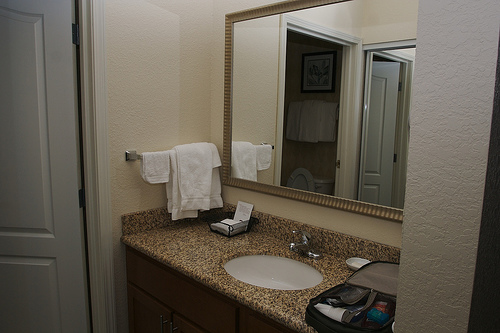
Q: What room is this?
A: It is a bathroom.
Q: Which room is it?
A: It is a bathroom.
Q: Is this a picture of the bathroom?
A: Yes, it is showing the bathroom.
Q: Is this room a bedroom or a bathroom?
A: It is a bathroom.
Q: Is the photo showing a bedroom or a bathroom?
A: It is showing a bathroom.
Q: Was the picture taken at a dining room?
A: No, the picture was taken in a bathroom.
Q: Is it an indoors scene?
A: Yes, it is indoors.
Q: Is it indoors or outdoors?
A: It is indoors.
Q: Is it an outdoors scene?
A: No, it is indoors.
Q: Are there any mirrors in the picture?
A: Yes, there is a mirror.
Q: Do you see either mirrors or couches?
A: Yes, there is a mirror.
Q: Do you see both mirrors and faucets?
A: Yes, there are both a mirror and a faucet.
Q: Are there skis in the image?
A: No, there are no skis.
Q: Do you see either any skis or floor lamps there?
A: No, there are no skis or floor lamps.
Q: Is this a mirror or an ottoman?
A: This is a mirror.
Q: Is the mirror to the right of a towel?
A: Yes, the mirror is to the right of a towel.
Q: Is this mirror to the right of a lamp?
A: No, the mirror is to the right of a towel.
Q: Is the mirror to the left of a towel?
A: No, the mirror is to the right of a towel.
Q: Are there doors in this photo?
A: Yes, there is a door.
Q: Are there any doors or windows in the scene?
A: Yes, there is a door.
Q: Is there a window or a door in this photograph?
A: Yes, there is a door.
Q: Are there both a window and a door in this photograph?
A: No, there is a door but no windows.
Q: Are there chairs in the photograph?
A: No, there are no chairs.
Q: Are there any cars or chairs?
A: No, there are no chairs or cars.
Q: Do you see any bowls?
A: No, there are no bowls.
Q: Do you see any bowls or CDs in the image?
A: No, there are no bowls or cds.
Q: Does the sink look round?
A: Yes, the sink is round.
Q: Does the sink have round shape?
A: Yes, the sink is round.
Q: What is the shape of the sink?
A: The sink is round.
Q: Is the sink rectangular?
A: No, the sink is round.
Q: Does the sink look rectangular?
A: No, the sink is round.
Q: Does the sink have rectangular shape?
A: No, the sink is round.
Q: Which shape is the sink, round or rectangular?
A: The sink is round.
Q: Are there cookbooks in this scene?
A: No, there are no cookbooks.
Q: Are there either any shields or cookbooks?
A: No, there are no cookbooks or shields.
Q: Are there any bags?
A: Yes, there is a bag.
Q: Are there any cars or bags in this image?
A: Yes, there is a bag.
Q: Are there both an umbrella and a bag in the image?
A: No, there is a bag but no umbrellas.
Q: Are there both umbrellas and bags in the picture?
A: No, there is a bag but no umbrellas.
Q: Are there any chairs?
A: No, there are no chairs.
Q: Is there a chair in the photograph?
A: No, there are no chairs.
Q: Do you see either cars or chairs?
A: No, there are no chairs or cars.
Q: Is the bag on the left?
A: No, the bag is on the right of the image.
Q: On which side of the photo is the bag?
A: The bag is on the right of the image.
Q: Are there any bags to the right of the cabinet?
A: Yes, there is a bag to the right of the cabinet.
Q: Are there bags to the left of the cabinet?
A: No, the bag is to the right of the cabinet.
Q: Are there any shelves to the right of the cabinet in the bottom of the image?
A: No, there is a bag to the right of the cabinet.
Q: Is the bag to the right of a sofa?
A: No, the bag is to the right of the cabinet.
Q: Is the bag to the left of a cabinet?
A: No, the bag is to the right of a cabinet.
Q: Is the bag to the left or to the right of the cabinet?
A: The bag is to the right of the cabinet.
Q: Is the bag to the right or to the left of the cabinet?
A: The bag is to the right of the cabinet.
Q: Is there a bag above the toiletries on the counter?
A: Yes, there is a bag above the toiletries.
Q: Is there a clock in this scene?
A: No, there are no clocks.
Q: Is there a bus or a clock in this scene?
A: No, there are no clocks or buses.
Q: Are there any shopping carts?
A: No, there are no shopping carts.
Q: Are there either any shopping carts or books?
A: No, there are no shopping carts or books.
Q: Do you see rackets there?
A: No, there are no rackets.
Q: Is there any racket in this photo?
A: No, there are no rackets.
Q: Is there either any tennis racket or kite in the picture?
A: No, there are no rackets or kites.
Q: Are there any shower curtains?
A: No, there are no shower curtains.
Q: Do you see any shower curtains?
A: No, there are no shower curtains.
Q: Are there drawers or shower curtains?
A: No, there are no shower curtains or drawers.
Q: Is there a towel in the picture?
A: Yes, there is a towel.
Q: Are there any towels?
A: Yes, there is a towel.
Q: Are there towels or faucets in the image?
A: Yes, there is a towel.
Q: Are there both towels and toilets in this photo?
A: Yes, there are both a towel and a toilet.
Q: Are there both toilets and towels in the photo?
A: Yes, there are both a towel and a toilet.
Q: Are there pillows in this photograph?
A: No, there are no pillows.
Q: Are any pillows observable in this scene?
A: No, there are no pillows.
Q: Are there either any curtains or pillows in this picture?
A: No, there are no pillows or curtains.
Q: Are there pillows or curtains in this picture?
A: No, there are no pillows or curtains.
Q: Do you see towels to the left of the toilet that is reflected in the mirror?
A: Yes, there is a towel to the left of the toilet.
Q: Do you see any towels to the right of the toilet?
A: No, the towel is to the left of the toilet.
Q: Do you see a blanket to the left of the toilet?
A: No, there is a towel to the left of the toilet.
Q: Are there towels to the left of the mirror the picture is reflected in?
A: Yes, there is a towel to the left of the mirror.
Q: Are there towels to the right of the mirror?
A: No, the towel is to the left of the mirror.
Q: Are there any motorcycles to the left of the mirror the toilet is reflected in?
A: No, there is a towel to the left of the mirror.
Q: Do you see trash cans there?
A: No, there are no trash cans.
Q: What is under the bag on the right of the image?
A: The toiletries are under the bag.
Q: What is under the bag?
A: The toiletries are under the bag.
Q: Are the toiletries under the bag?
A: Yes, the toiletries are under the bag.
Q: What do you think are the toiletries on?
A: The toiletries are on the counter.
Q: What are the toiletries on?
A: The toiletries are on the counter.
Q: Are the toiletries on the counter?
A: Yes, the toiletries are on the counter.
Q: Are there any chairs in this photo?
A: No, there are no chairs.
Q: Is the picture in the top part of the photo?
A: Yes, the picture is in the top of the image.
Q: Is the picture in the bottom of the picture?
A: No, the picture is in the top of the image.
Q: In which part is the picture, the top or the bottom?
A: The picture is in the top of the image.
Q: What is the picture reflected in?
A: The picture is reflected in the mirror.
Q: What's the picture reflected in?
A: The picture is reflected in the mirror.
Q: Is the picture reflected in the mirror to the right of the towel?
A: Yes, the picture is reflected in the mirror.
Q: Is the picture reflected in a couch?
A: No, the picture is reflected in the mirror.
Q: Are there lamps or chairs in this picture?
A: No, there are no chairs or lamps.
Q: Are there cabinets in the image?
A: Yes, there is a cabinet.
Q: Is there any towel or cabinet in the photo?
A: Yes, there is a cabinet.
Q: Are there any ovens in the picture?
A: No, there are no ovens.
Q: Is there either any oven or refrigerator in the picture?
A: No, there are no ovens or refrigerators.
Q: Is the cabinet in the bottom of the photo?
A: Yes, the cabinet is in the bottom of the image.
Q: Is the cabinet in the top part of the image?
A: No, the cabinet is in the bottom of the image.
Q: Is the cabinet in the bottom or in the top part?
A: The cabinet is in the bottom of the image.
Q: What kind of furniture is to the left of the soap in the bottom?
A: The piece of furniture is a cabinet.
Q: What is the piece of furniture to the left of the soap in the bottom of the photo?
A: The piece of furniture is a cabinet.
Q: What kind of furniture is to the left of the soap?
A: The piece of furniture is a cabinet.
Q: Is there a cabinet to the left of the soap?
A: Yes, there is a cabinet to the left of the soap.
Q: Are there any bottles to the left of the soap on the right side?
A: No, there is a cabinet to the left of the soap.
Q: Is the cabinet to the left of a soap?
A: Yes, the cabinet is to the left of a soap.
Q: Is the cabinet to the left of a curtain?
A: No, the cabinet is to the left of a soap.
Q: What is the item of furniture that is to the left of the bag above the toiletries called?
A: The piece of furniture is a cabinet.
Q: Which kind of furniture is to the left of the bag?
A: The piece of furniture is a cabinet.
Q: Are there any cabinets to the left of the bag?
A: Yes, there is a cabinet to the left of the bag.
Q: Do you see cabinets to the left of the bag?
A: Yes, there is a cabinet to the left of the bag.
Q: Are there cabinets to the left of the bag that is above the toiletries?
A: Yes, there is a cabinet to the left of the bag.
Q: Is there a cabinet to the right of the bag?
A: No, the cabinet is to the left of the bag.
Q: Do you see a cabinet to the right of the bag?
A: No, the cabinet is to the left of the bag.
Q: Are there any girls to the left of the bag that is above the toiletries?
A: No, there is a cabinet to the left of the bag.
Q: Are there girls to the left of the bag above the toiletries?
A: No, there is a cabinet to the left of the bag.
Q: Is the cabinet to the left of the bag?
A: Yes, the cabinet is to the left of the bag.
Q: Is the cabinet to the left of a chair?
A: No, the cabinet is to the left of the bag.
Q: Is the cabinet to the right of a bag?
A: No, the cabinet is to the left of a bag.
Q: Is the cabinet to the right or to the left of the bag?
A: The cabinet is to the left of the bag.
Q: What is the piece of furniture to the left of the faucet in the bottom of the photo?
A: The piece of furniture is a cabinet.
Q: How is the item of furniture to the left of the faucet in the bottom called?
A: The piece of furniture is a cabinet.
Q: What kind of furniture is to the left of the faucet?
A: The piece of furniture is a cabinet.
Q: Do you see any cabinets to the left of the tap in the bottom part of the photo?
A: Yes, there is a cabinet to the left of the tap.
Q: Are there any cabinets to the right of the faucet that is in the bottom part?
A: No, the cabinet is to the left of the tap.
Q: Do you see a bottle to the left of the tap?
A: No, there is a cabinet to the left of the tap.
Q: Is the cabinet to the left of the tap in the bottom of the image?
A: Yes, the cabinet is to the left of the faucet.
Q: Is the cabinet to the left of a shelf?
A: No, the cabinet is to the left of the faucet.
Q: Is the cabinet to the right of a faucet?
A: No, the cabinet is to the left of a faucet.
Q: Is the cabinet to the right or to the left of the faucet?
A: The cabinet is to the left of the faucet.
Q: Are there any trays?
A: No, there are no trays.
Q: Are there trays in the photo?
A: No, there are no trays.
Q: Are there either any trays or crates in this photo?
A: No, there are no trays or crates.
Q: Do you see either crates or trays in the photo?
A: No, there are no trays or crates.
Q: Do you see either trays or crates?
A: No, there are no trays or crates.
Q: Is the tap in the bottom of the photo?
A: Yes, the tap is in the bottom of the image.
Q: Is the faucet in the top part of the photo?
A: No, the faucet is in the bottom of the image.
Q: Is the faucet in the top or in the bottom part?
A: The faucet is in the bottom of the image.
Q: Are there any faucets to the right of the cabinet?
A: Yes, there is a faucet to the right of the cabinet.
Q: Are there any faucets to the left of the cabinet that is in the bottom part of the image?
A: No, the faucet is to the right of the cabinet.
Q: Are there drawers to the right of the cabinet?
A: No, there is a faucet to the right of the cabinet.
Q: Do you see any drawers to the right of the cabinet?
A: No, there is a faucet to the right of the cabinet.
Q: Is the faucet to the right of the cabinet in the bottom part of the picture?
A: Yes, the faucet is to the right of the cabinet.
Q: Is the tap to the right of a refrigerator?
A: No, the tap is to the right of the cabinet.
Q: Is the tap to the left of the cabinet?
A: No, the tap is to the right of the cabinet.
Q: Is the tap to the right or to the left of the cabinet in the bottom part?
A: The tap is to the right of the cabinet.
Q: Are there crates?
A: No, there are no crates.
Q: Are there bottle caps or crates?
A: No, there are no crates or bottle caps.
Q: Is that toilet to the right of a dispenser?
A: No, the toilet is to the right of the towel.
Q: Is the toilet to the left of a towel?
A: No, the toilet is to the right of a towel.